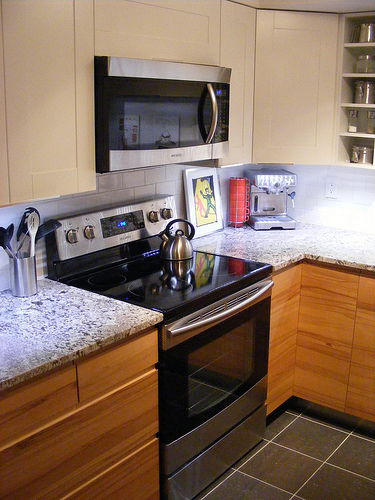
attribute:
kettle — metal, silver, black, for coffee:
[158, 218, 195, 263]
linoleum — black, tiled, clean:
[186, 408, 374, 500]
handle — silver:
[170, 280, 273, 343]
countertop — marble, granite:
[0, 217, 374, 393]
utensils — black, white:
[2, 207, 62, 258]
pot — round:
[5, 251, 37, 298]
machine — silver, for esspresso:
[245, 168, 296, 232]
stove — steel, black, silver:
[46, 194, 273, 499]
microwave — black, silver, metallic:
[93, 55, 233, 172]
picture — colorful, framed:
[183, 168, 225, 239]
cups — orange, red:
[229, 176, 248, 230]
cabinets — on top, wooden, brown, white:
[1, 1, 374, 207]